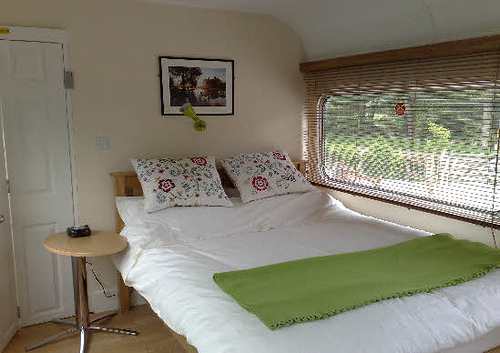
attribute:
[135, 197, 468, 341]
comforter — white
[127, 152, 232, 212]
pillow — floral 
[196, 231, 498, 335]
blanket — green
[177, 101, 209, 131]
stuffed toy — green 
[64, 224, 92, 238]
clock — small, black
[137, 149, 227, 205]
pillow — embroidered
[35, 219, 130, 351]
table — round